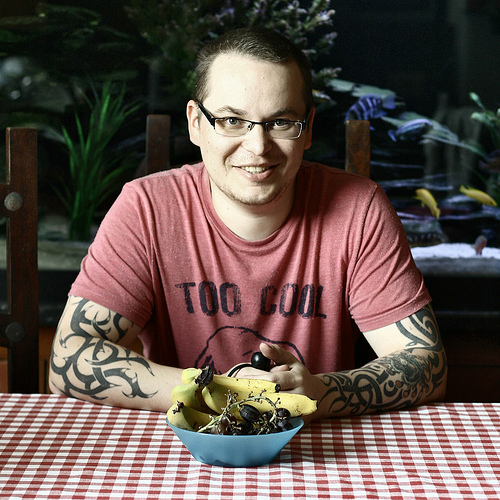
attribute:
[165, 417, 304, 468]
bowl — blue, plastic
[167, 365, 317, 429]
bananas — yellow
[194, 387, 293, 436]
grapes — red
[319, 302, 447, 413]
tattoos — black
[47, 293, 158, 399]
tattoos — black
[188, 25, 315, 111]
hair — short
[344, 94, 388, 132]
fish — purple, black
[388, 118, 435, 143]
fish — purple, black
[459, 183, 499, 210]
fish — yellow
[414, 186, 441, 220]
fish — yellow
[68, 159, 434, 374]
shirt — red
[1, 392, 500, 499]
tablecloth — red, checkered, white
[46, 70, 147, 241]
plant — small, green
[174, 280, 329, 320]
too cool — black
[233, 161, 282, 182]
lips — lucious, big, pink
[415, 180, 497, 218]
fish — yellow, swimming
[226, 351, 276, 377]
object — black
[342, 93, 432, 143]
fish — blue, striped, swimming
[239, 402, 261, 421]
grape — purple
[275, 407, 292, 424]
grape — purple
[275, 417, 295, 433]
grape — purple